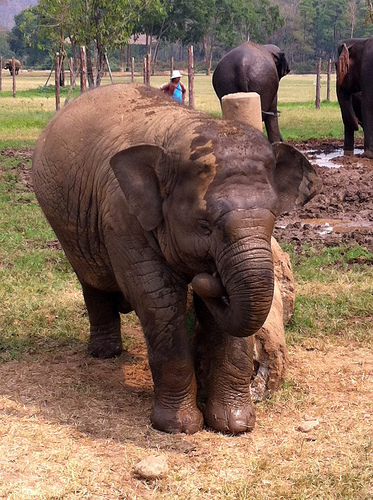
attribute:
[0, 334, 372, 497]
brown grass — dry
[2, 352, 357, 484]
grass — brown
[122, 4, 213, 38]
leaves — green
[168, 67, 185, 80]
hat — white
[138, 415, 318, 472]
rocks — small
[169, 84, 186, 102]
shirt — light blue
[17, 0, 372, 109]
trees — short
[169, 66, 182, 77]
cap — white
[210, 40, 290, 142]
animal — black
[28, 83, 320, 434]
elephant — small, brown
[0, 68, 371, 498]
ground — arid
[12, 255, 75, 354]
grass — brown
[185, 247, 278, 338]
trunk — curled